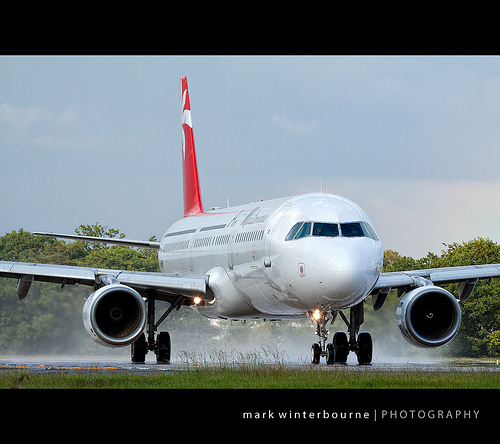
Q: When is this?
A: Daytime.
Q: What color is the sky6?
A: Blue.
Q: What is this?
A: Plane.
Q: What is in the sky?
A: Clouds.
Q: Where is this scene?
A: Leaving the runway.